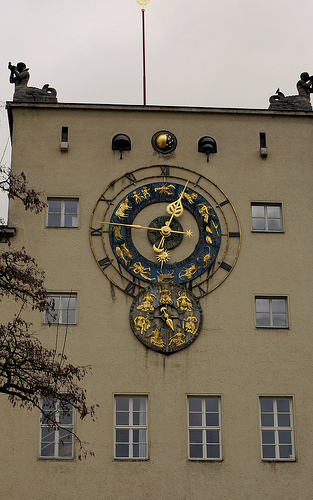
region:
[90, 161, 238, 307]
clock on side of building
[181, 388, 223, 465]
window on the building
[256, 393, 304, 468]
window on the building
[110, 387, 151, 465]
window on the building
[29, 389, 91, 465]
window on the building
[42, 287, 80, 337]
window on the building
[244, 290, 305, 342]
window on the building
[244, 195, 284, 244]
window on the building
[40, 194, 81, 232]
window on the building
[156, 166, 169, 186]
roman numeral on the clock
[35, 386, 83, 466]
The window is rectangular.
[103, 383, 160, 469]
The window is rectangular.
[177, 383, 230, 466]
The window is rectangular.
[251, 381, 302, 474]
The window is rectangular.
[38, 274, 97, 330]
The window is square.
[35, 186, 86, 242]
The window is square.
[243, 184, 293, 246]
The window is square.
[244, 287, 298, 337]
The window is square.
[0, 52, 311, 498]
The building is tan.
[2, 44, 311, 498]
Two figures are on top of the building.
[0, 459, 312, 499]
dirty tan stucco building face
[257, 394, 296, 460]
inset square window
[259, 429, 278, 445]
square window frame with white trim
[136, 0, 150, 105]
red lightning rod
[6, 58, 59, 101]
dark stone sculpture of mythical figure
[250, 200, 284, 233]
small four frame glass window reflecting murky grey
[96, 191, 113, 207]
roman numeral ten iron work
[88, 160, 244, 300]
large elegant clock on building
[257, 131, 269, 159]
small buttress in building face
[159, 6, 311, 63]
dark white grey sky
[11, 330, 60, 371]
reddish leaves on tree branch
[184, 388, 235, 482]
group of eight small windows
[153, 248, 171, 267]
golden sun figure on clock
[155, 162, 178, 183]
roman numeral twelve on clock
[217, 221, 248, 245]
roman numeral three on clock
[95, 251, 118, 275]
roman numeral eight on clock face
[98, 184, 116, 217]
roman numeral ten on clock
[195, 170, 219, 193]
roman numeral one on clock face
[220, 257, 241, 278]
roman numeral four on clock face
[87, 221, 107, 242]
roman numeral nine on the clock face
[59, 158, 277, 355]
LARGE CLOCK ON SIDE OF BUILDING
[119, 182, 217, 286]
ZODIAC SIGNS ON FACE OF CLOCK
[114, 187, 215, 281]
HANDS OF CLOCK ARE GOLD COLORED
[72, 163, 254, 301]
ROMAN NUMERALS ARE ON CLOCK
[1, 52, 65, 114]
STATUE ON TOP OF BUILDING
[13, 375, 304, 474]
WINDOWS ON THE BOTTOM OF BUILDING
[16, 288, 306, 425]
BUILDING IS BEIGE IN COLOR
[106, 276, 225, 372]
FIGURES FROM MYTHOLOGY SHOWN ON SIDE OF BUILDING UNDER CLOCK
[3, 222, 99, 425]
TREE BESIDE THE BUILDING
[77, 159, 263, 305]
CLOCK IS ROUND IN SHAPE